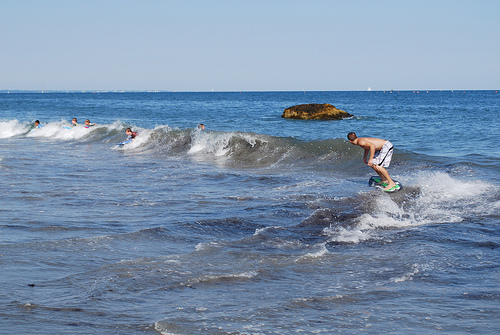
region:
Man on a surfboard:
[331, 119, 410, 212]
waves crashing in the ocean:
[208, 116, 303, 174]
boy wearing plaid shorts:
[366, 133, 397, 179]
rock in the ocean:
[276, 90, 354, 130]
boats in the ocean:
[358, 74, 467, 114]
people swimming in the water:
[79, 115, 91, 131]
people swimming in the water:
[64, 114, 79, 129]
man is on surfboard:
[327, 115, 424, 207]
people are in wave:
[1, 117, 308, 167]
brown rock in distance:
[278, 110, 369, 132]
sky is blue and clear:
[167, 0, 432, 51]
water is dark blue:
[374, 93, 455, 140]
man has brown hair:
[344, 133, 396, 173]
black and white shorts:
[350, 141, 401, 165]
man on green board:
[360, 143, 400, 205]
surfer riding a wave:
[333, 126, 398, 198]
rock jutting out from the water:
[279, 98, 354, 123]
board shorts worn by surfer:
[368, 140, 395, 165]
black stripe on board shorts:
[377, 145, 393, 165]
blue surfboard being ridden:
[369, 173, 401, 191]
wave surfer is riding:
[12, 110, 459, 222]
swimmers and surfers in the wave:
[23, 101, 218, 156]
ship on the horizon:
[362, 82, 374, 90]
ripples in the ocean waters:
[77, 78, 494, 128]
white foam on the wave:
[8, 118, 250, 163]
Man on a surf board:
[331, 125, 406, 221]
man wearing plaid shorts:
[370, 136, 400, 167]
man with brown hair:
[344, 124, 358, 144]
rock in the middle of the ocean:
[276, 89, 354, 125]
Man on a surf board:
[108, 121, 149, 146]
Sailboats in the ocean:
[361, 80, 456, 95]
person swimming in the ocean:
[187, 116, 207, 138]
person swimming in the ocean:
[111, 117, 146, 147]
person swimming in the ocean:
[61, 109, 103, 136]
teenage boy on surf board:
[344, 129, 400, 196]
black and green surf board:
[369, 170, 404, 196]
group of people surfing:
[27, 110, 210, 148]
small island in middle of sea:
[284, 101, 354, 126]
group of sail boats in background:
[364, 83, 464, 99]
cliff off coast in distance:
[2, 84, 172, 96]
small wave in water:
[1, 110, 488, 242]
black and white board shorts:
[371, 138, 396, 173]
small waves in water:
[26, 213, 453, 334]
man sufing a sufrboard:
[336, 130, 413, 195]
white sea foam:
[36, 125, 79, 136]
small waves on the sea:
[11, 113, 329, 177]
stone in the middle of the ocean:
[285, 97, 350, 122]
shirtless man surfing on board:
[340, 129, 401, 184]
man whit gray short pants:
[335, 129, 399, 215]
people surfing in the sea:
[60, 109, 218, 139]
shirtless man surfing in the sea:
[344, 124, 417, 220]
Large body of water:
[88, 194, 199, 294]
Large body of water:
[283, 258, 386, 317]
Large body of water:
[33, 170, 125, 221]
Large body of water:
[365, 260, 457, 317]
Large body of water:
[330, 281, 421, 324]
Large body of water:
[338, 249, 423, 304]